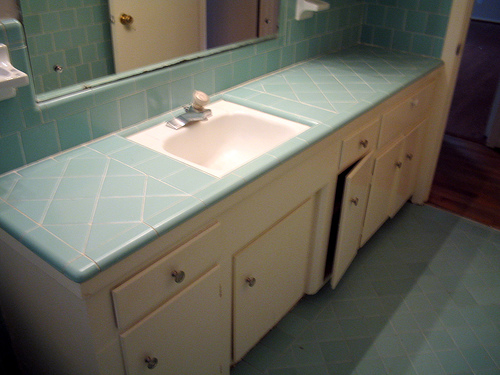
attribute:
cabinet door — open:
[283, 129, 410, 300]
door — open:
[325, 151, 370, 298]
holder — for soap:
[296, 3, 328, 22]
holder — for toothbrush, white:
[1, 41, 30, 106]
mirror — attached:
[14, 2, 283, 107]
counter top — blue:
[4, 29, 444, 289]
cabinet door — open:
[320, 154, 390, 301]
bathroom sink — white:
[152, 110, 297, 175]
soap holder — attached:
[1, 45, 29, 110]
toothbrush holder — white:
[0, 41, 31, 100]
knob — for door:
[344, 191, 356, 215]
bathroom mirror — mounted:
[17, 2, 291, 103]